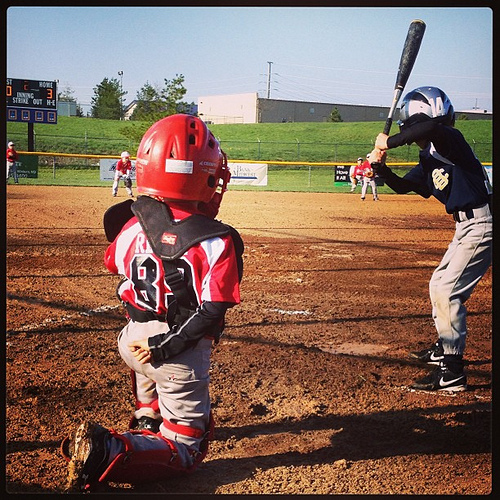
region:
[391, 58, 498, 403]
This is a person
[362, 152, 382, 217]
This is a person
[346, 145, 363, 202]
This is a person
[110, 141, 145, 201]
This is a person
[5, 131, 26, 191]
This is a person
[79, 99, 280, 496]
This is a person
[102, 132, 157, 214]
This is a person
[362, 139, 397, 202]
This is a person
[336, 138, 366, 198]
This is a person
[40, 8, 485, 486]
baseball players on field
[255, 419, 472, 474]
shadow of the boy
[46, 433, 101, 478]
bottom of the shoe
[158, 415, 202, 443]
stripe on the pants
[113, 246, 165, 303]
number on the jersey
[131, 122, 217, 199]
the helmet is red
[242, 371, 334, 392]
dirt on the field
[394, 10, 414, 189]
baseball bat in hands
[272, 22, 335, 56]
the sky is mostly clear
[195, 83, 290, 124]
building on the hill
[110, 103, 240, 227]
red helmet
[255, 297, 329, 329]
white line drawn on ground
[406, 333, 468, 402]
black and white sneakers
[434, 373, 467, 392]
white nike logo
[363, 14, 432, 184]
black and silver bat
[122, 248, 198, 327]
black number on back of jersey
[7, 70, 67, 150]
black score board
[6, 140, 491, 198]
yellow border on top of fence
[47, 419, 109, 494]
bottom of cleat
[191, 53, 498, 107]
power lines in sky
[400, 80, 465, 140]
Silver and black baseball helmet.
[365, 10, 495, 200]
Person wearing black and silver, holding a bat.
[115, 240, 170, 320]
Black number eight on a baseball jersey.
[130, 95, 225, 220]
Red baseball helmet.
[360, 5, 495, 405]
Playing baseball on red earth.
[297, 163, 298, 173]
Hand behind back during baseball game.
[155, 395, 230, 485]
Baseball player kneeling in red dirt.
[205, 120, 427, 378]
Grass and red clay dirt.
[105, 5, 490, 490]
Five children playing baseball.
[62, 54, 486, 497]
Children playing baseball in clay, beneath a grass covered hill.